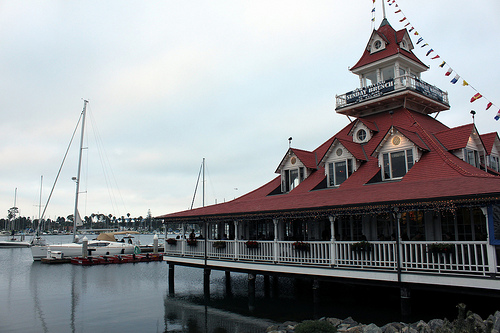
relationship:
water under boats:
[0, 232, 497, 331] [4, 221, 161, 259]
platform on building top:
[333, 74, 451, 118] [334, 15, 456, 120]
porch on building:
[154, 231, 499, 311] [32, 89, 494, 319]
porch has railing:
[154, 231, 499, 311] [201, 224, 452, 296]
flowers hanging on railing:
[290, 240, 312, 252] [163, 237, 497, 279]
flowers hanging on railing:
[243, 238, 260, 248] [163, 237, 497, 279]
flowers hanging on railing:
[214, 240, 226, 250] [163, 237, 497, 279]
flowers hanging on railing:
[187, 238, 198, 247] [163, 237, 497, 279]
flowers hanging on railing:
[168, 238, 177, 245] [163, 237, 497, 279]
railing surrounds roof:
[328, 74, 449, 112] [345, 21, 424, 71]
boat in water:
[28, 95, 166, 265] [6, 249, 184, 330]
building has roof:
[172, 196, 497, 296] [158, 103, 497, 232]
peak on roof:
[366, 24, 391, 55] [158, 103, 497, 232]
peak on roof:
[269, 145, 310, 177] [158, 103, 497, 232]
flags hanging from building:
[369, 2, 499, 121] [148, 0, 499, 299]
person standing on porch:
[188, 227, 198, 241] [163, 237, 498, 287]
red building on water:
[155, 20, 494, 285] [18, 267, 91, 311]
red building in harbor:
[155, 20, 494, 285] [3, 70, 166, 253]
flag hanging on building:
[470, 91, 482, 103] [148, 0, 499, 299]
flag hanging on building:
[445, 66, 453, 77] [148, 0, 499, 299]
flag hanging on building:
[493, 107, 498, 121] [148, 0, 499, 299]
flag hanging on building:
[424, 49, 434, 56] [148, 0, 499, 299]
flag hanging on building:
[392, 9, 402, 15] [148, 0, 499, 299]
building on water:
[148, 0, 499, 299] [0, 232, 497, 331]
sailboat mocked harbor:
[4, 187, 30, 255] [5, 234, 221, 330]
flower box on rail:
[293, 241, 310, 251] [159, 237, 485, 274]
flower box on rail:
[349, 242, 374, 251] [159, 237, 485, 274]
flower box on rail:
[427, 240, 456, 253] [159, 237, 485, 274]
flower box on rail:
[245, 240, 262, 250] [159, 237, 485, 274]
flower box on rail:
[210, 240, 227, 250] [159, 237, 485, 274]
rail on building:
[159, 237, 485, 274] [163, 15, 487, 272]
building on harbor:
[163, 15, 487, 272] [7, 202, 487, 322]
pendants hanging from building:
[389, 2, 498, 116] [148, 0, 499, 299]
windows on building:
[270, 143, 427, 193] [212, 189, 497, 330]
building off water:
[148, 0, 499, 299] [1, 235, 265, 332]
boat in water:
[28, 95, 166, 265] [0, 235, 223, 330]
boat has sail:
[30, 104, 157, 276] [71, 209, 89, 229]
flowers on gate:
[343, 234, 378, 258] [241, 230, 487, 268]